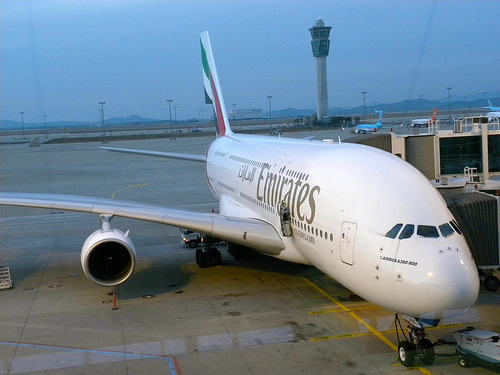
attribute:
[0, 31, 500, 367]
airplane — white, here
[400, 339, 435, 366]
wheels — black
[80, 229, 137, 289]
engine` — white, cylindrical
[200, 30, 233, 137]
tail — black, striped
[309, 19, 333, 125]
tower — air traffic, black, tall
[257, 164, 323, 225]
name — black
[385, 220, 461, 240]
windows — dark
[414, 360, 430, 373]
line — yellow, on the ground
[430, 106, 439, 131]
stick — orange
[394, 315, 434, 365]
gear — landing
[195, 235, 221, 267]
gear — landing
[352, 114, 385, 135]
airplane — blue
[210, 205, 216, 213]
cone — orange, on ground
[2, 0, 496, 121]
sky — cloudy